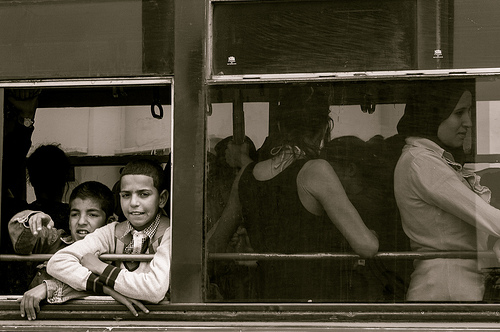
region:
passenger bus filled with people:
[1, 1, 498, 328]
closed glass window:
[204, 75, 499, 302]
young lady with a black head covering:
[392, 78, 499, 303]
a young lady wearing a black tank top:
[203, 80, 382, 299]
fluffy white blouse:
[391, 135, 498, 298]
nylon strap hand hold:
[148, 102, 166, 120]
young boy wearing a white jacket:
[46, 155, 171, 316]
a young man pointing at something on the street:
[6, 178, 114, 320]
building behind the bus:
[19, 96, 499, 210]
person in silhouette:
[23, 140, 78, 229]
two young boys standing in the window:
[7, 165, 169, 308]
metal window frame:
[177, 0, 203, 302]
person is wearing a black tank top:
[240, 155, 324, 294]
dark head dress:
[395, 83, 470, 141]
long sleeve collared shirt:
[395, 138, 496, 302]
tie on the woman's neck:
[269, 143, 301, 172]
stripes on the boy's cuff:
[85, 263, 117, 292]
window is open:
[4, 80, 171, 300]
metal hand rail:
[210, 251, 497, 258]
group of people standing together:
[15, 89, 494, 297]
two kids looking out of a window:
[8, 163, 175, 318]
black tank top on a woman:
[230, 136, 341, 290]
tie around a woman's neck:
[265, 140, 302, 174]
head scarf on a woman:
[390, 76, 478, 154]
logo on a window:
[222, 48, 242, 68]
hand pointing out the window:
[18, 204, 59, 239]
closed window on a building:
[200, 78, 495, 309]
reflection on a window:
[468, 108, 498, 281]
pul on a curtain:
[135, 88, 172, 128]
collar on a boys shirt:
[117, 222, 157, 249]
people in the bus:
[8, 75, 498, 306]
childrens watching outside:
[46, 171, 167, 256]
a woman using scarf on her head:
[401, 80, 481, 138]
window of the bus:
[219, 53, 492, 277]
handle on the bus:
[143, 99, 172, 121]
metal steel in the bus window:
[219, 241, 499, 272]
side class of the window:
[11, 28, 171, 73]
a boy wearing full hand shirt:
[70, 225, 187, 298]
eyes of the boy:
[122, 189, 151, 199]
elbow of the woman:
[343, 212, 385, 258]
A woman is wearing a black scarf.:
[394, 80, 479, 162]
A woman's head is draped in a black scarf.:
[390, 66, 482, 149]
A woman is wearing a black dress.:
[241, 145, 339, 315]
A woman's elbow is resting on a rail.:
[297, 161, 387, 273]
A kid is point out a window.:
[9, 196, 96, 265]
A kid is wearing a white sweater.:
[76, 180, 193, 314]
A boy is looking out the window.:
[76, 157, 191, 310]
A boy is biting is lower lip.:
[96, 166, 169, 226]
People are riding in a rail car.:
[23, 63, 493, 297]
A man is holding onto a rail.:
[4, 83, 50, 150]